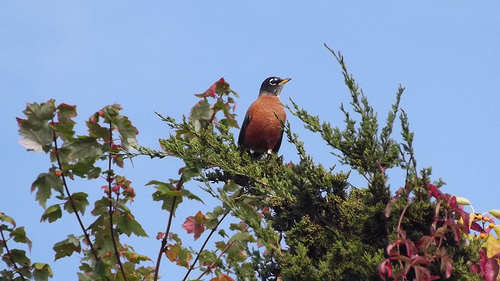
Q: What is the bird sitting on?
A: A tree.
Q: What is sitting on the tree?
A: A bird.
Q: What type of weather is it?
A: Sunny.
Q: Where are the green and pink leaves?
A: On the tree.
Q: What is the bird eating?
A: Nothing.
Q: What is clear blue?
A: The sky.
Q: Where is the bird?
A: At the top of a tree.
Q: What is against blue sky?
A: Broad green leaves.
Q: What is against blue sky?
A: Thin brown branches.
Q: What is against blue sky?
A: Pointy evergreen leaves.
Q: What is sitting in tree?
A: A bird.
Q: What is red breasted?
A: A bird.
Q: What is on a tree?
A: A wild bird.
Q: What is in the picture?
A: Spring foliage from several trees.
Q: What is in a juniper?
A: A bird.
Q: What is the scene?
A: Nature scene on a sunny day.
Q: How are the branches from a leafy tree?
A: Thin.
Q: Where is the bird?
A: On a pine tree branch.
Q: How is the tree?
A: Deciduous with red and green leaves.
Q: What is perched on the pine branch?
A: A bird.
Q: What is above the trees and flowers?
A: A bird.